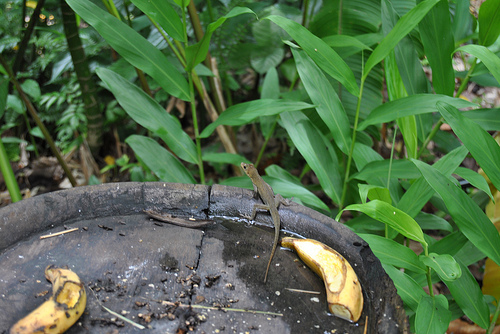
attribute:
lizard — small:
[199, 147, 333, 217]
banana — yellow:
[286, 226, 388, 314]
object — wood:
[154, 189, 249, 259]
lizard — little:
[255, 164, 289, 259]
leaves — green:
[351, 117, 495, 261]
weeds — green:
[351, 117, 495, 261]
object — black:
[165, 193, 226, 298]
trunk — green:
[45, 17, 139, 149]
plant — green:
[45, 17, 139, 149]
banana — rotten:
[29, 271, 96, 331]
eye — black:
[235, 157, 276, 198]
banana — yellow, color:
[245, 224, 409, 332]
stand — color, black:
[61, 207, 298, 314]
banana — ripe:
[266, 224, 390, 321]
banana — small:
[278, 240, 379, 324]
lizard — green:
[222, 164, 300, 265]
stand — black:
[54, 203, 292, 333]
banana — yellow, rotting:
[278, 235, 364, 319]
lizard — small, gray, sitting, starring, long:
[233, 160, 298, 288]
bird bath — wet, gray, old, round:
[5, 178, 388, 333]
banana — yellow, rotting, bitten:
[12, 249, 88, 331]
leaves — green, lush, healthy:
[289, 14, 492, 182]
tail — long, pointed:
[265, 221, 283, 285]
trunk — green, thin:
[54, 13, 109, 133]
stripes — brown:
[69, 46, 87, 66]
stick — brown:
[33, 219, 90, 248]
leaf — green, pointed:
[94, 65, 201, 163]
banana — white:
[324, 300, 359, 325]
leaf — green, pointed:
[405, 151, 500, 249]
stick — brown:
[282, 279, 324, 297]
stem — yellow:
[280, 233, 298, 251]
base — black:
[3, 184, 404, 332]